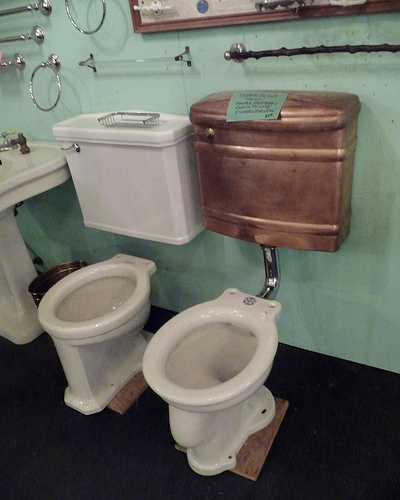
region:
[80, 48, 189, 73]
The clear towel holder bar above the white water tank.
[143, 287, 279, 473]
The toilet bowl below the gold water tank.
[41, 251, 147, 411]
The toilet bowl below the white water tank.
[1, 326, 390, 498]
The black floor in the room.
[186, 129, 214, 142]
The gold handle flusher on the gold water tank.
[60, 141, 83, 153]
The silver flusher handle on the white water tank.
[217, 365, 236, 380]
The hole inside of the toilet below the gold water tank.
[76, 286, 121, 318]
The inside of the toilet beneath the white water tank.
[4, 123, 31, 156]
The handles of the sink.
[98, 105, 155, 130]
The silver tray on top of the white water tank lid.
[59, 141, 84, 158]
handle that flushes toilet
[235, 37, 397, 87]
black towel rack in bathroom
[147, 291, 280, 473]
white porcelin toilet in bathroom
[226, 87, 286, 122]
written note on bronze toilet base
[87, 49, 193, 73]
clear towel rack hanging in bathroom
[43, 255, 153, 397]
white porcelin toilet in bathroom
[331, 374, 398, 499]
blue carpet in bathroom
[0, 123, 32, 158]
faucet for the bathroom sink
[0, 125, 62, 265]
white porcelin bathroom sink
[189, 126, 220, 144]
bronze handle for flushing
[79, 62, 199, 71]
bar on the wall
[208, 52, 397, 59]
bar on the wall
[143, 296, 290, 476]
commode on the floor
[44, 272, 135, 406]
commode on the floor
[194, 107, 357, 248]
tank of the toilet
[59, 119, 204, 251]
tank of the toilet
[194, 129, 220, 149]
handle of the toilet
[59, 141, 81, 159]
handle of the toilet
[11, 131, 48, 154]
handle of the sink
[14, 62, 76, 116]
towel ring on wall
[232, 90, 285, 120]
The green paper on the gold water tank.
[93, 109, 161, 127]
The silver tray on the white water tank.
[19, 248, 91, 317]
The silver can next to the toilet.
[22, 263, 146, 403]
The toilet under the white water tank.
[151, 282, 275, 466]
The toilet under the gold water tank.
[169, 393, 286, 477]
The piece of wood under the toilet that has the gold water tank.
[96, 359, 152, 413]
The wood under the toilet beneath the white water tank.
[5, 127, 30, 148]
The knobs on the sink.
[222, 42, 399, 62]
The black towel rod on the wall.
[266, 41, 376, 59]
black towel holder on wall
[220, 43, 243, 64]
silver handle on towel holder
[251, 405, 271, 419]
black bolts on the white toilet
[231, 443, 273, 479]
piece of brown board on the floor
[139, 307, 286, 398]
white lid on toilet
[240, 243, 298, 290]
silver frame on toilet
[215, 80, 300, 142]
small piece of green paper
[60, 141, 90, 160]
silver handle on toilet tank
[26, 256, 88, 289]
lid of shiny silver waste basket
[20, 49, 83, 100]
silver rings on the wall